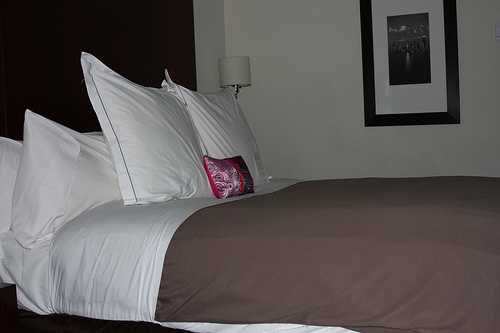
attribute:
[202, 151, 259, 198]
pillow — small, decorative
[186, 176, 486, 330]
comforter — taupe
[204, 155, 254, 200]
pillow — small, pink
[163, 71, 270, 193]
pillows — white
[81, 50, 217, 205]
pillows — white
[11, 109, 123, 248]
pillows — white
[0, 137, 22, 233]
pillows — white